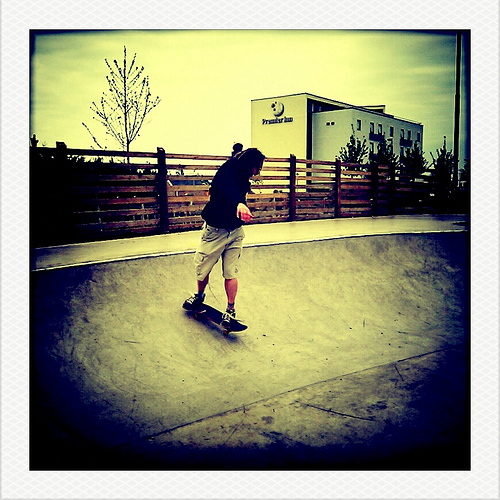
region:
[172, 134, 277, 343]
man on a skateboard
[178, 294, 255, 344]
feet on the skateboard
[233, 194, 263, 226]
hand sticking out of the sleeve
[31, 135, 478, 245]
fence along the top of the ramp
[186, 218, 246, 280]
tan cargo shorts on the legs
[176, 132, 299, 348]
man skateboarding on a ramp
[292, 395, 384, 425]
scuff mark on the ramp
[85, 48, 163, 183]
tree behind the fence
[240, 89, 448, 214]
building behind the fence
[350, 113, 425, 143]
windows on the side of the building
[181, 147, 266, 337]
a man riding on a skateboard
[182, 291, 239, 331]
black shoes on a man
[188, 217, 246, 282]
a man wearing cargo shorts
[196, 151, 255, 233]
a man wearing a black hoodie jacket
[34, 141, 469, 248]
a wooden fence near a skateboard park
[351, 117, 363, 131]
a window on a building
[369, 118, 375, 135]
a window on a building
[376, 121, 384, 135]
a window on a building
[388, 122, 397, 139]
a window on a building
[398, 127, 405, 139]
a window on a building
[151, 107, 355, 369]
the man is skateboarding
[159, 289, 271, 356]
the skateboard is black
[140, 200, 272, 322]
the man is wearing shorts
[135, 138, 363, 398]
the man is on a ramp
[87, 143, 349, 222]
a fence behind the man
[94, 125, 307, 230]
the fence is brown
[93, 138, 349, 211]
the fence is made of wood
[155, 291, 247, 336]
the sneakers are black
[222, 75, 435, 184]
a building in the background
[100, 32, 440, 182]
the sky is overcast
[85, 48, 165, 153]
tree with no leaves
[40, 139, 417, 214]
wood fence around skate park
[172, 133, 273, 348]
man riding a skateboard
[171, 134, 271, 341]
man wearing tan shorts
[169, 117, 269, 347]
man wearing black sweatshirt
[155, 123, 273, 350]
man wearing black shoes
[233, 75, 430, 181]
building with windows at the top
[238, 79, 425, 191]
building with words on the top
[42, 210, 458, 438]
ramp at the skate park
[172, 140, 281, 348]
A man skateboarding in a skate bowl